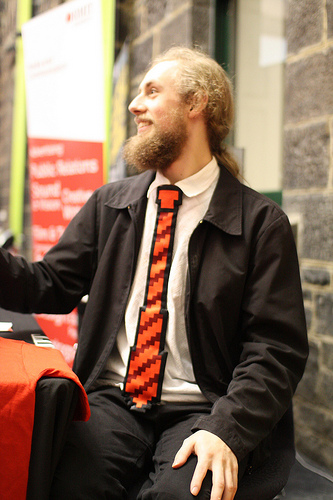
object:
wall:
[287, 3, 331, 212]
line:
[288, 36, 328, 61]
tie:
[123, 188, 185, 410]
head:
[118, 48, 234, 176]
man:
[0, 45, 312, 499]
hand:
[172, 429, 240, 498]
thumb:
[171, 442, 189, 469]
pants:
[51, 381, 276, 500]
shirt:
[99, 159, 222, 407]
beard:
[122, 104, 188, 175]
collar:
[174, 154, 219, 199]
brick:
[283, 0, 323, 44]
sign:
[21, 0, 109, 357]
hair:
[149, 46, 241, 178]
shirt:
[0, 334, 96, 500]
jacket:
[1, 160, 312, 499]